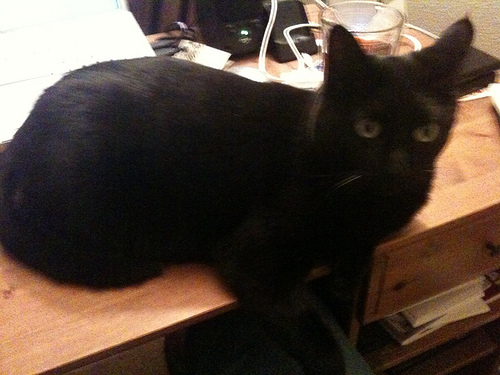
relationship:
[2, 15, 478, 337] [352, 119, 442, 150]
cat has eyes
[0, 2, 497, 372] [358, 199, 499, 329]
desk has drawer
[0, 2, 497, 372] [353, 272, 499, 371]
desk has shelving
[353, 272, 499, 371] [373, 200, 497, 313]
shelving under drawer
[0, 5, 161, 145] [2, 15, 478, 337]
laptop screen behind cat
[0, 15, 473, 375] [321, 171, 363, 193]
cat has whiskers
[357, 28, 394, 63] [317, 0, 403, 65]
liquid in glass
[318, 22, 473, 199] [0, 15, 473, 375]
cat head of cat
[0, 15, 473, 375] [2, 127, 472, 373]
cat perched on desk